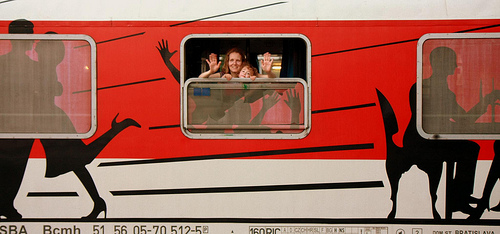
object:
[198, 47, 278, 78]
adult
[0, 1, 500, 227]
artwork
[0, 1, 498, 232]
car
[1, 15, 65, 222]
silhouette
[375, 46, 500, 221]
image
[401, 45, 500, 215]
man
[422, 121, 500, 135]
table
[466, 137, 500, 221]
someone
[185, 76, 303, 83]
ledge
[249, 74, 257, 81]
hand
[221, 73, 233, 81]
hand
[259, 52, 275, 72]
hand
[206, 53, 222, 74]
hand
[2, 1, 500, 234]
wall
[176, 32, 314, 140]
window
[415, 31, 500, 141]
window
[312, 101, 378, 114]
line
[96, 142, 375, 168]
line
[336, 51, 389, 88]
surface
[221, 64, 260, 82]
child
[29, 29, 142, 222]
silhouette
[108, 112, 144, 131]
heel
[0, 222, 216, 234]
lettering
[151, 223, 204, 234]
number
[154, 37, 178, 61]
hand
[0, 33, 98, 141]
windows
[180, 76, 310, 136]
covering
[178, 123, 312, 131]
ledge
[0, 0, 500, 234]
photo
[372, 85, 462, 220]
black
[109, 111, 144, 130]
painting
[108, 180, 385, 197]
line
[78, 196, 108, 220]
feet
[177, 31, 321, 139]
open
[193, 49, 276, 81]
smiling